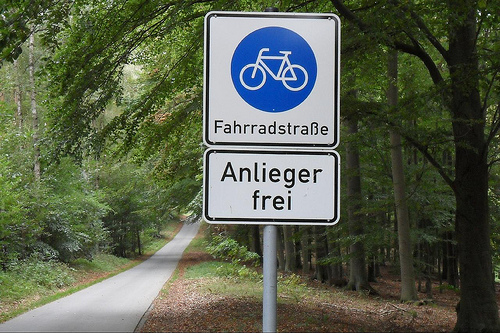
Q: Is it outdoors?
A: Yes, it is outdoors.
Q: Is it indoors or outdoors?
A: It is outdoors.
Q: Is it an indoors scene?
A: No, it is outdoors.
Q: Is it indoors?
A: No, it is outdoors.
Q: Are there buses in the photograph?
A: No, there are no buses.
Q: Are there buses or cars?
A: No, there are no buses or cars.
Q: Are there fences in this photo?
A: No, there are no fences.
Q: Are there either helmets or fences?
A: No, there are no fences or helmets.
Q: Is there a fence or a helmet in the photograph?
A: No, there are no fences or helmets.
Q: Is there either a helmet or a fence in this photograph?
A: No, there are no fences or helmets.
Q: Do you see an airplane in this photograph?
A: Yes, there is an airplane.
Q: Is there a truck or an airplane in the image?
A: Yes, there is an airplane.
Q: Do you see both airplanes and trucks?
A: No, there is an airplane but no trucks.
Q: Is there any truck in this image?
A: No, there are no trucks.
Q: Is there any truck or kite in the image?
A: No, there are no trucks or kites.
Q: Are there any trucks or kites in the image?
A: No, there are no trucks or kites.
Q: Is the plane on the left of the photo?
A: Yes, the plane is on the left of the image.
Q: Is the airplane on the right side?
A: No, the airplane is on the left of the image.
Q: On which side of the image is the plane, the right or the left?
A: The plane is on the left of the image.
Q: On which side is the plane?
A: The plane is on the left of the image.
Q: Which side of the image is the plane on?
A: The plane is on the left of the image.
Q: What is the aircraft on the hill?
A: The aircraft is an airplane.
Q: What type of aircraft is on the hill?
A: The aircraft is an airplane.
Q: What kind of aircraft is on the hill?
A: The aircraft is an airplane.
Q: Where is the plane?
A: The plane is on the hill.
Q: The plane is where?
A: The plane is on the hill.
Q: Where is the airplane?
A: The plane is on the hill.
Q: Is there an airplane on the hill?
A: Yes, there is an airplane on the hill.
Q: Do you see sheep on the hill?
A: No, there is an airplane on the hill.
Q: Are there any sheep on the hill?
A: No, there is an airplane on the hill.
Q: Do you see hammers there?
A: No, there are no hammers.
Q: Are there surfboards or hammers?
A: No, there are no hammers or surfboards.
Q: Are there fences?
A: No, there are no fences.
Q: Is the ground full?
A: Yes, the ground is full.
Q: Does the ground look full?
A: Yes, the ground is full.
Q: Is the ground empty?
A: No, the ground is full.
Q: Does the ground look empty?
A: No, the ground is full.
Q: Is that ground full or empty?
A: The ground is full.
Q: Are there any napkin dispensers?
A: No, there are no napkin dispensers.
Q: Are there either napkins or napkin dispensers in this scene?
A: No, there are no napkin dispensers or napkins.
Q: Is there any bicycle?
A: Yes, there is a bicycle.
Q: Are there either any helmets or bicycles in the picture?
A: Yes, there is a bicycle.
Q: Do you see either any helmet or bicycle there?
A: Yes, there is a bicycle.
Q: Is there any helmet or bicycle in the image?
A: Yes, there is a bicycle.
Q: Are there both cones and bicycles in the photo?
A: No, there is a bicycle but no cones.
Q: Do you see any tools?
A: No, there are no tools.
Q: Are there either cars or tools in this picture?
A: No, there are no tools or cars.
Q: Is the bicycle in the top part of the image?
A: Yes, the bicycle is in the top of the image.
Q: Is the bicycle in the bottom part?
A: No, the bicycle is in the top of the image.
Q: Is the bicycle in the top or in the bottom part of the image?
A: The bicycle is in the top of the image.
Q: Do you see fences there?
A: No, there are no fences.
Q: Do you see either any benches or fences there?
A: No, there are no fences or benches.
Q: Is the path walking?
A: Yes, the path is walking.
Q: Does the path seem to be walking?
A: Yes, the path is walking.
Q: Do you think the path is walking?
A: Yes, the path is walking.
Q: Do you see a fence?
A: No, there are no fences.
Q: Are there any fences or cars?
A: No, there are no fences or cars.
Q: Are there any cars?
A: No, there are no cars.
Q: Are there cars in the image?
A: No, there are no cars.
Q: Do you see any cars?
A: No, there are no cars.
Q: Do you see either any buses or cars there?
A: No, there are no cars or buses.